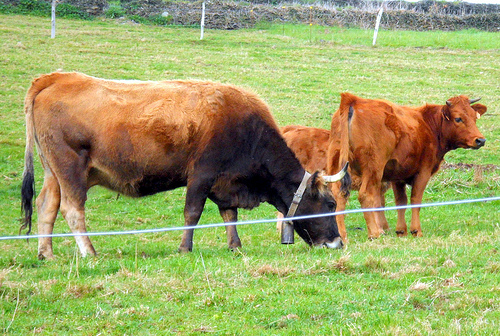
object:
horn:
[321, 161, 350, 183]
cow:
[19, 71, 350, 262]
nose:
[475, 137, 486, 146]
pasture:
[110, 44, 480, 75]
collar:
[280, 171, 312, 245]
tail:
[14, 75, 50, 242]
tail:
[335, 93, 354, 193]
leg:
[177, 156, 211, 255]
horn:
[468, 96, 485, 104]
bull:
[326, 91, 489, 242]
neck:
[270, 126, 304, 226]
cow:
[326, 92, 489, 242]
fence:
[40, 1, 469, 57]